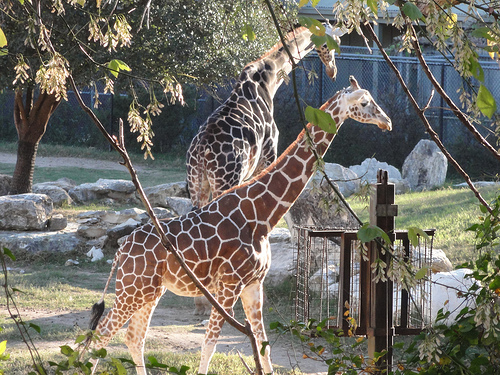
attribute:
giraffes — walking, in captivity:
[94, 60, 363, 319]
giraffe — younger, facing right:
[96, 90, 433, 368]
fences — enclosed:
[16, 34, 491, 170]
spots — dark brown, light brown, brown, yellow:
[204, 205, 243, 239]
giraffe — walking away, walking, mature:
[198, 27, 307, 171]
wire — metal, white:
[312, 223, 421, 329]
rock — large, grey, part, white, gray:
[0, 185, 56, 241]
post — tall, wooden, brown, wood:
[373, 176, 392, 368]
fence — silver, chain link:
[31, 25, 489, 174]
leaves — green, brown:
[342, 14, 369, 43]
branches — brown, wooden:
[376, 17, 499, 108]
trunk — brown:
[4, 93, 46, 176]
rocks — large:
[15, 144, 489, 262]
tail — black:
[81, 239, 131, 331]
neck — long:
[254, 0, 291, 94]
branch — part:
[47, 99, 64, 132]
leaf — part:
[474, 88, 499, 115]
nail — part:
[380, 208, 386, 210]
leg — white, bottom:
[230, 274, 283, 361]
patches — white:
[236, 288, 262, 309]